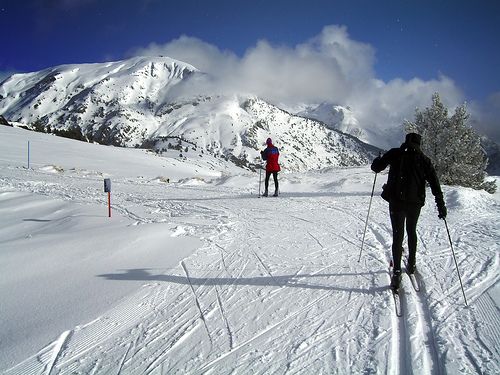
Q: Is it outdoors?
A: Yes, it is outdoors.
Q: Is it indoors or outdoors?
A: It is outdoors.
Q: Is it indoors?
A: No, it is outdoors.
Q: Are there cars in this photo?
A: No, there are no cars.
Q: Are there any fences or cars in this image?
A: No, there are no cars or fences.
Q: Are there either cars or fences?
A: No, there are no cars or fences.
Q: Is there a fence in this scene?
A: No, there are no fences.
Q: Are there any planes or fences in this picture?
A: No, there are no fences or planes.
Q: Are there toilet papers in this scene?
A: No, there are no toilet papers.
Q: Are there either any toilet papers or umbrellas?
A: No, there are no toilet papers or umbrellas.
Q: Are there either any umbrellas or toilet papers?
A: No, there are no toilet papers or umbrellas.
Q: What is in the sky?
A: The clouds are in the sky.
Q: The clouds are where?
A: The clouds are in the sky.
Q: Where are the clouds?
A: The clouds are in the sky.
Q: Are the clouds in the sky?
A: Yes, the clouds are in the sky.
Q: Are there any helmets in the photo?
A: No, there are no helmets.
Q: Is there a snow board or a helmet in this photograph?
A: No, there are no helmets or snowboards.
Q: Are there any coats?
A: Yes, there is a coat.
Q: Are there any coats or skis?
A: Yes, there is a coat.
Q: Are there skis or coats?
A: Yes, there is a coat.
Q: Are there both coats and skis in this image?
A: Yes, there are both a coat and skis.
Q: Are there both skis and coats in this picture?
A: Yes, there are both a coat and skis.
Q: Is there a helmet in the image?
A: No, there are no helmets.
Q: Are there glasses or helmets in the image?
A: No, there are no helmets or glasses.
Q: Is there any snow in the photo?
A: Yes, there is snow.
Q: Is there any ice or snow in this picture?
A: Yes, there is snow.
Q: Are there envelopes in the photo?
A: No, there are no envelopes.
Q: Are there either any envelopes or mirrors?
A: No, there are no envelopes or mirrors.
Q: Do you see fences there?
A: No, there are no fences.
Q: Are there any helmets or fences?
A: No, there are no fences or helmets.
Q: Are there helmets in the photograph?
A: No, there are no helmets.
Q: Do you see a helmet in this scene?
A: No, there are no helmets.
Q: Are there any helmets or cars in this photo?
A: No, there are no helmets or cars.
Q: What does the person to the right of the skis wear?
A: The person wears a jacket.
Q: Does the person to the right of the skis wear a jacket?
A: Yes, the person wears a jacket.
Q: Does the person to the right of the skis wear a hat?
A: No, the person wears a jacket.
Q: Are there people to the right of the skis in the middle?
A: Yes, there is a person to the right of the skis.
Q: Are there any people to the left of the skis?
A: No, the person is to the right of the skis.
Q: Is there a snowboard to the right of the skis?
A: No, there is a person to the right of the skis.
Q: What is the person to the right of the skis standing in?
A: The person is standing in the snow.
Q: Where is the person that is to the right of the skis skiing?
A: The person is skiing in the snow.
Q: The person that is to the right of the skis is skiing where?
A: The person is skiing in the snow.